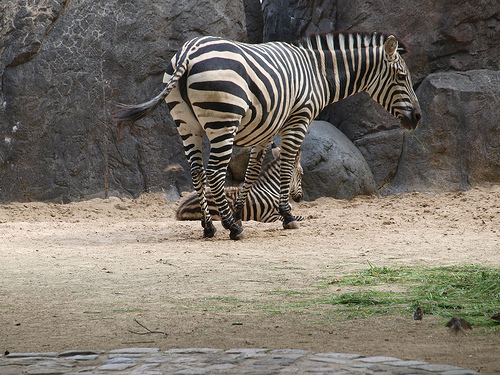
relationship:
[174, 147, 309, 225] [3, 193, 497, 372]
zebra laying down on ground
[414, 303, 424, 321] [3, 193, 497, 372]
bird perched on ground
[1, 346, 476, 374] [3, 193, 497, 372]
stones buried in ground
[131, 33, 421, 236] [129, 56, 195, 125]
zebra swinging tail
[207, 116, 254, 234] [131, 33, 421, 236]
leg of zebra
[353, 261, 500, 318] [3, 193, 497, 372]
grass on ground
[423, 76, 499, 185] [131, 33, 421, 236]
boulder behind zebra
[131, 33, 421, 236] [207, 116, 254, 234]
zebra has leg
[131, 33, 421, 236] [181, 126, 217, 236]
zebra has leg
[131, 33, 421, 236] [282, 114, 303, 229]
zebra has leg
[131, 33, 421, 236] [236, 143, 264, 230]
zebra has leg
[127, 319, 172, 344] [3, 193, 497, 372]
stick on top of ground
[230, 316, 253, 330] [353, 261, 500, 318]
leaves near grass